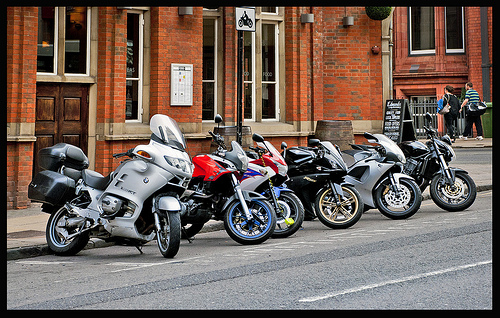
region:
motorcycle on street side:
[28, 114, 157, 239]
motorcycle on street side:
[195, 120, 254, 235]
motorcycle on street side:
[251, 137, 298, 232]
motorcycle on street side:
[288, 133, 358, 241]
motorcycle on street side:
[412, 115, 478, 202]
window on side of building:
[124, 14, 149, 123]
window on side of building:
[200, 12, 214, 125]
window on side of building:
[252, 19, 282, 130]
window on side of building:
[405, 13, 433, 50]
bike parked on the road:
[25, 111, 183, 261]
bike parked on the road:
[186, 133, 276, 243]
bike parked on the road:
[235, 127, 301, 237]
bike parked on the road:
[285, 138, 365, 227]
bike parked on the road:
[335, 123, 416, 218]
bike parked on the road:
[395, 122, 476, 209]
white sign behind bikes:
[173, 65, 190, 105]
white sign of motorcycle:
[233, 10, 253, 27]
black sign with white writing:
[386, 98, 416, 139]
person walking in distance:
[438, 79, 465, 137]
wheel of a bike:
[145, 199, 200, 261]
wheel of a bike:
[223, 185, 285, 247]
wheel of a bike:
[179, 220, 213, 244]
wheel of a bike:
[30, 195, 97, 258]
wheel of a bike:
[268, 191, 320, 245]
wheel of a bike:
[310, 178, 365, 230]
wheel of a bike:
[357, 174, 417, 236]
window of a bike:
[131, 110, 196, 153]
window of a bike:
[365, 120, 415, 162]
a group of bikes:
[45, 102, 484, 268]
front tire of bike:
[151, 181, 208, 286]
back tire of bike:
[47, 197, 101, 269]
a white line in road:
[266, 248, 391, 314]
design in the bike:
[228, 193, 280, 246]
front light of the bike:
[143, 140, 197, 172]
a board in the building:
[158, 45, 213, 126]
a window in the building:
[226, 19, 305, 164]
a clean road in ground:
[187, 255, 284, 290]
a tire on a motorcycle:
[159, 211, 184, 260]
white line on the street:
[363, 267, 397, 305]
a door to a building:
[43, 87, 108, 142]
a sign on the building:
[166, 59, 200, 120]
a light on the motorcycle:
[165, 151, 192, 179]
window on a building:
[255, 62, 280, 102]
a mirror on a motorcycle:
[254, 123, 269, 158]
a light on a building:
[297, 13, 324, 40]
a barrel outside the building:
[321, 107, 363, 152]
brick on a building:
[322, 61, 364, 114]